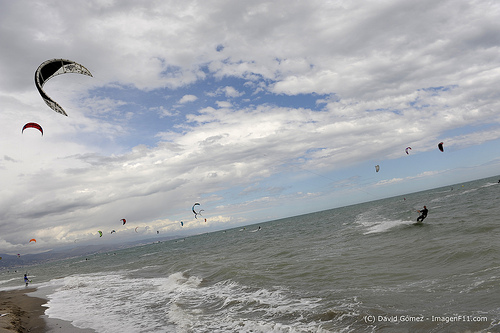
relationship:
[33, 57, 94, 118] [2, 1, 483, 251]
kite flying in sky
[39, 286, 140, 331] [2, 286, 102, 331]
wave rolling on sand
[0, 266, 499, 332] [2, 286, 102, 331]
wave rolling on sand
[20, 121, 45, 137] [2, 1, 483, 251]
kite flying in sky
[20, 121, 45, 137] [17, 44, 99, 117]
kite behind kite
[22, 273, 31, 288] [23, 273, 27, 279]
people in shirt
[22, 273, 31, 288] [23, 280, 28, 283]
people in shorts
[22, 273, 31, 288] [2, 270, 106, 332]
people on beach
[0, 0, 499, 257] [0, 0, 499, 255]
sky full of clouds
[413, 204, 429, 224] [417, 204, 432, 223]
man wearing wetsuit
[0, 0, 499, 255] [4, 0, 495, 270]
clouds in sky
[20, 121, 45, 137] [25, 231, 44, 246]
kite near kite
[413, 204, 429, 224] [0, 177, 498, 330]
man kitesurfing in water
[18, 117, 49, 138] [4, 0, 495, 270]
kite in sky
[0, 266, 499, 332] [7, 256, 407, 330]
wave are in shore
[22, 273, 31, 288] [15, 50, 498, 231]
people standing below kites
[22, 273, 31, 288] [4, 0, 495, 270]
people standing below sky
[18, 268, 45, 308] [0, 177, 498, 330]
people in water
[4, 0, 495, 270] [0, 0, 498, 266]
sky in clouds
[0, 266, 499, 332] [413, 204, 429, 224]
wave in front of man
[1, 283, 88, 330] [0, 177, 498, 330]
sand along water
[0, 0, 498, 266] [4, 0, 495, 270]
clouds are in sky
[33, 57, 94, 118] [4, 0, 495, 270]
kite in sky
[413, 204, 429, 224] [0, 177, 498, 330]
man in water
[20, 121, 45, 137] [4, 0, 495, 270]
kite are in sky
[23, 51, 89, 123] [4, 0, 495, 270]
kite in sky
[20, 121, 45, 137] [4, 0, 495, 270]
kite in sky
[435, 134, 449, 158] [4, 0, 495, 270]
kite in sky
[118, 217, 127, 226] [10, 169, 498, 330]
windsurfing sail above ocean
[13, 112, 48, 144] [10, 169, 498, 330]
windsurfing sail above ocean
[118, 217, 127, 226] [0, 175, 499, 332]
windsurfing sail above water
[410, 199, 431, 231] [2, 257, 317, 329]
man parasailing near shore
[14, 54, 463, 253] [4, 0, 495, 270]
parasails filling sky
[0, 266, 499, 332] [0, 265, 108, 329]
wave lapping shore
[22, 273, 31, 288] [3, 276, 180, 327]
people on shore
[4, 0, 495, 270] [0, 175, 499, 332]
sky on water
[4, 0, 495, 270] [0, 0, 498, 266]
sky through clouds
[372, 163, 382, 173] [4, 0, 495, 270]
parasails are in sky